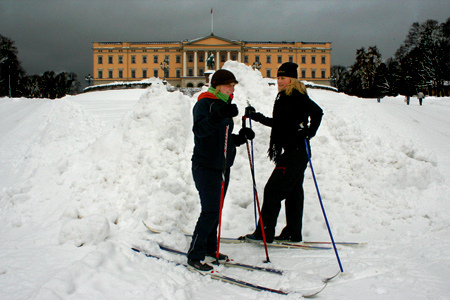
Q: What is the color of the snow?
A: White.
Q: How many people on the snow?
A: Two.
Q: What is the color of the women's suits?
A: Black.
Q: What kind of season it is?
A: Winter.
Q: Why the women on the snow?
A: To ski.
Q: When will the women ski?
A: Later.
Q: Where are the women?
A: On the snow.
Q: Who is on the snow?
A: Women.